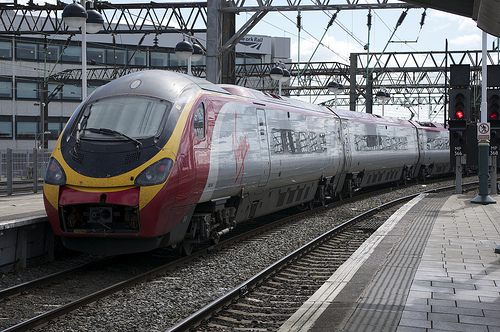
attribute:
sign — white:
[203, 115, 261, 206]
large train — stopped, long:
[41, 74, 248, 250]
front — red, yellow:
[55, 53, 215, 217]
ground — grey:
[109, 261, 220, 300]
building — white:
[11, 30, 154, 75]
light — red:
[442, 57, 481, 165]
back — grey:
[433, 144, 450, 167]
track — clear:
[339, 191, 403, 222]